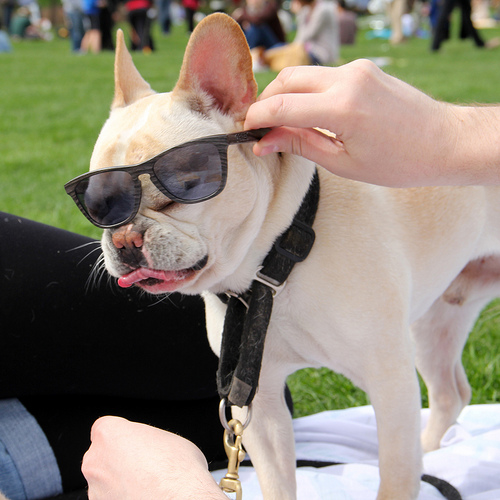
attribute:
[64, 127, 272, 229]
sunglasses — black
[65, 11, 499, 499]
dog — white, blonde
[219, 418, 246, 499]
clasp — golden, gold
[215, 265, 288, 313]
buckle — silver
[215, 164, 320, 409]
dog collar — black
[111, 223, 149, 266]
nose — pink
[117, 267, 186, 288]
tongue — pink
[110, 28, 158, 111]
right ear — white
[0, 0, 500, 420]
grass — green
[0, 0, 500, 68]
group of people — picnicing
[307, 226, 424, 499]
front left leg — white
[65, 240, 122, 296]
group of whiskers — white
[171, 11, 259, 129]
left ear — white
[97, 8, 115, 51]
pants — black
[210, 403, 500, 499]
blanket — white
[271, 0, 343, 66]
person — sitting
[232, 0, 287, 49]
person — sitting